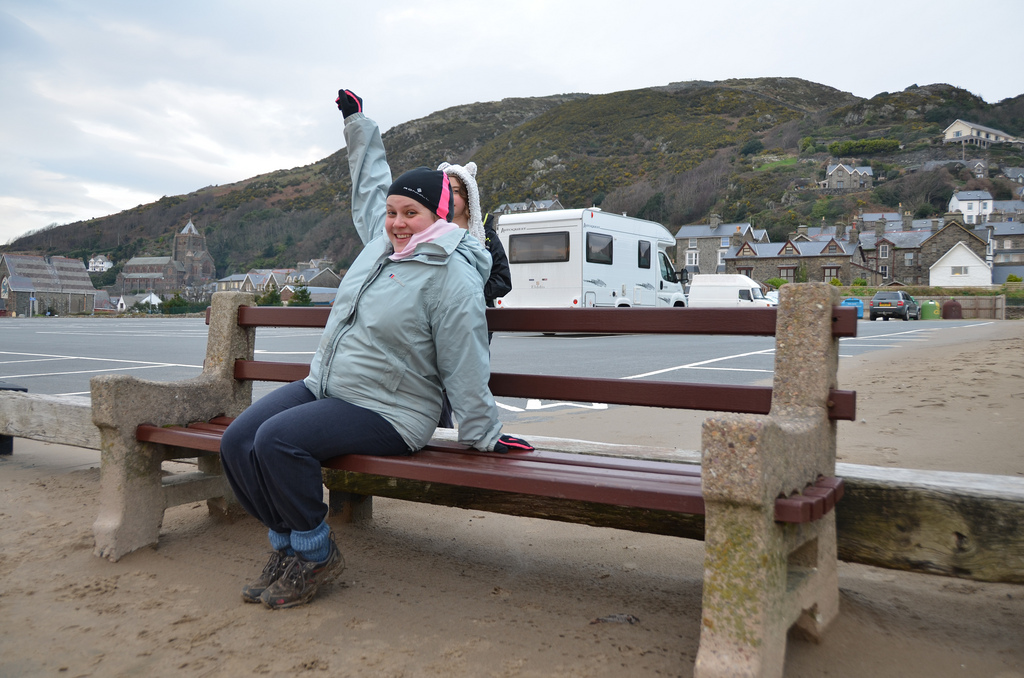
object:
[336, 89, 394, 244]
arm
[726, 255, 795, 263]
wall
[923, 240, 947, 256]
wall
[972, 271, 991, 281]
wall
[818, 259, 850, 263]
wall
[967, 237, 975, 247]
wall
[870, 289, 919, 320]
car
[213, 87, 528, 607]
female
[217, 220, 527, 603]
clothing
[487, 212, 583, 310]
wall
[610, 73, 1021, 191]
hill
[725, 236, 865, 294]
building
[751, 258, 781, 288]
wall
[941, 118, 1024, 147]
building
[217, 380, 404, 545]
pants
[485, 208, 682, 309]
bench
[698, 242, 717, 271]
wall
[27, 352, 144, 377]
white line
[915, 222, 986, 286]
wall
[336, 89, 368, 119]
glove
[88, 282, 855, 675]
bench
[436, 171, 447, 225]
stripe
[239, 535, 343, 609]
shoes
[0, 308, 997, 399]
parking lot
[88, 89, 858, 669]
woman/bench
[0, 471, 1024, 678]
sand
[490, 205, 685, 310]
camper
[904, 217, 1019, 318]
building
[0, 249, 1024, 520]
lot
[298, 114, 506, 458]
jacket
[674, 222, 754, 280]
homes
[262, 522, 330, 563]
socks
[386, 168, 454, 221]
accent